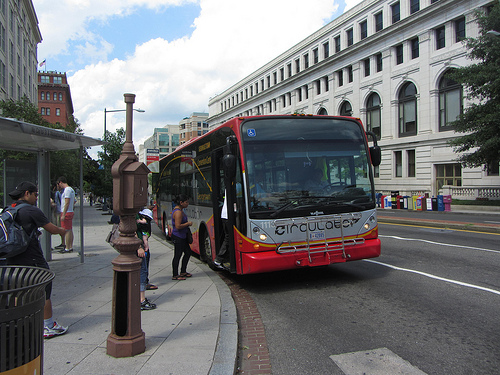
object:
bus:
[144, 111, 386, 278]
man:
[52, 175, 80, 255]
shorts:
[58, 210, 76, 230]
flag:
[37, 54, 47, 69]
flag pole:
[43, 65, 48, 72]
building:
[34, 68, 75, 131]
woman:
[166, 193, 195, 285]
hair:
[171, 191, 186, 206]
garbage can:
[0, 263, 59, 375]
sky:
[35, 3, 350, 150]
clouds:
[83, 17, 262, 103]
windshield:
[237, 115, 376, 214]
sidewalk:
[39, 196, 239, 372]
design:
[232, 277, 274, 374]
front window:
[239, 117, 374, 217]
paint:
[370, 231, 498, 294]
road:
[248, 218, 497, 373]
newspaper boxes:
[379, 187, 456, 211]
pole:
[101, 90, 154, 359]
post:
[77, 145, 86, 259]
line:
[364, 229, 499, 295]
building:
[205, 1, 499, 208]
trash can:
[2, 263, 56, 372]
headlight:
[258, 230, 267, 243]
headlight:
[362, 219, 373, 232]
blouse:
[168, 207, 194, 240]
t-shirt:
[59, 184, 76, 216]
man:
[1, 184, 69, 340]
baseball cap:
[10, 178, 38, 203]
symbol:
[244, 124, 258, 140]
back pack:
[0, 200, 35, 257]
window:
[361, 90, 386, 143]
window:
[390, 75, 419, 141]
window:
[430, 60, 472, 136]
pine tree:
[447, 5, 500, 173]